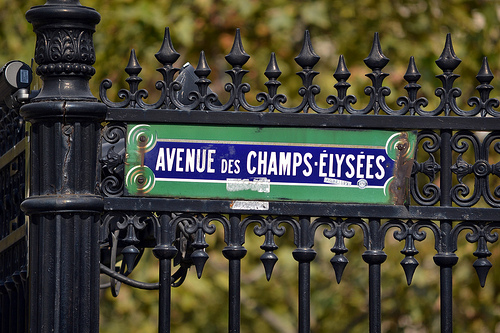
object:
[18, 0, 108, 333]
fence post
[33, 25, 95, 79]
decoration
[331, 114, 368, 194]
ground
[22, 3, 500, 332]
fence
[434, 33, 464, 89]
spike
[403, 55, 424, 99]
spike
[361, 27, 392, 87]
spike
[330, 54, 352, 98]
spike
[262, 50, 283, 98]
spike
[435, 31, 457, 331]
spoke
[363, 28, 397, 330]
spoke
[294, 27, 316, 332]
spoke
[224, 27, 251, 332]
spoke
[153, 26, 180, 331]
spoke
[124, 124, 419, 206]
green sign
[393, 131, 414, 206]
rust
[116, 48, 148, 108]
decorative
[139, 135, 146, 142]
bolt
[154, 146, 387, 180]
letters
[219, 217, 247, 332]
banister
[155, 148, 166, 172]
white letters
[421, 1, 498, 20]
green foliage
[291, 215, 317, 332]
banister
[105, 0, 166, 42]
foliage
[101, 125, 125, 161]
camera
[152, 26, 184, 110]
decoration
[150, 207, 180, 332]
banister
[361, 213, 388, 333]
banister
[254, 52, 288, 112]
part